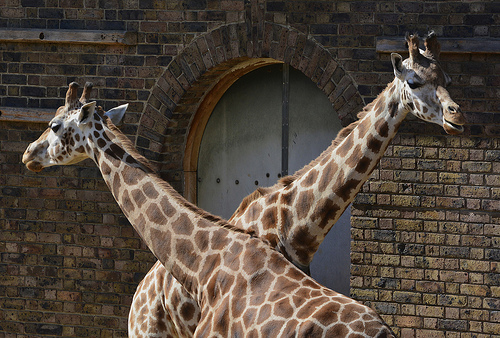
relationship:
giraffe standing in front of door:
[25, 81, 398, 337] [184, 55, 351, 337]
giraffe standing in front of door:
[126, 30, 467, 336] [184, 55, 351, 337]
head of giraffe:
[19, 81, 130, 173] [25, 81, 398, 337]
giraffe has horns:
[25, 81, 398, 337] [57, 81, 95, 107]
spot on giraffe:
[151, 225, 171, 267] [25, 81, 398, 337]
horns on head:
[57, 81, 95, 107] [19, 81, 130, 173]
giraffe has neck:
[25, 81, 398, 337] [89, 109, 252, 296]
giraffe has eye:
[25, 81, 398, 337] [50, 123, 67, 132]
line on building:
[0, 29, 499, 46] [4, 3, 497, 336]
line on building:
[1, 109, 120, 122] [4, 3, 497, 336]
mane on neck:
[91, 103, 254, 240] [89, 109, 252, 296]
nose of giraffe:
[21, 145, 38, 158] [25, 81, 398, 337]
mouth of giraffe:
[22, 153, 55, 172] [25, 81, 398, 337]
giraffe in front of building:
[25, 81, 398, 337] [4, 3, 497, 336]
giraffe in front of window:
[25, 81, 398, 337] [185, 58, 355, 336]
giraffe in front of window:
[126, 30, 467, 336] [185, 58, 355, 336]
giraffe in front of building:
[126, 30, 467, 336] [4, 3, 497, 336]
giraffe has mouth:
[126, 30, 467, 336] [443, 113, 464, 140]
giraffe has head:
[25, 81, 398, 337] [19, 81, 130, 173]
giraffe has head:
[126, 30, 467, 336] [390, 29, 466, 133]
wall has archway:
[3, 2, 495, 337] [119, 14, 376, 335]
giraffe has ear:
[25, 81, 398, 337] [69, 101, 100, 127]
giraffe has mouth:
[25, 81, 398, 337] [22, 153, 55, 172]